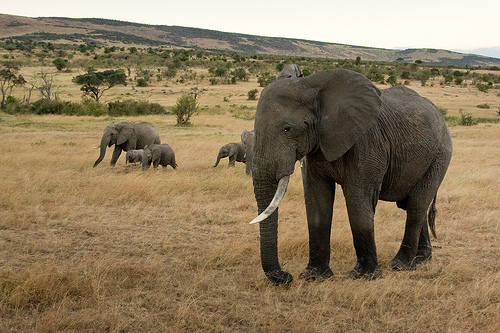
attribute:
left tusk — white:
[249, 181, 293, 224]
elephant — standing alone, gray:
[250, 67, 452, 291]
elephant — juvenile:
[144, 143, 180, 169]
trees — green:
[0, 31, 499, 122]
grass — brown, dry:
[1, 136, 498, 332]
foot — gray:
[297, 260, 332, 279]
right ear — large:
[274, 63, 300, 79]